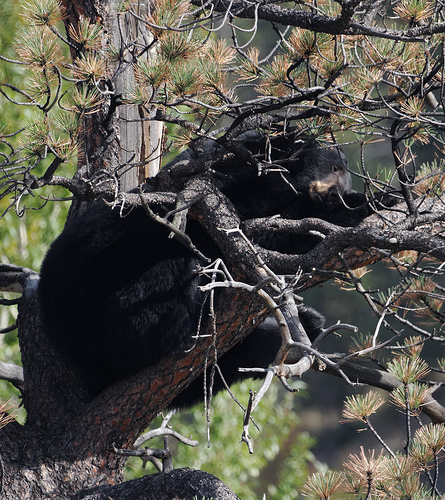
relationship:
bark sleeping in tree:
[0, 441, 124, 500] [0, 1, 443, 498]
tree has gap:
[6, 88, 430, 497] [131, 35, 150, 187]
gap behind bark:
[131, 35, 150, 187] [0, 441, 124, 500]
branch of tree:
[0, 0, 445, 456] [85, 43, 153, 152]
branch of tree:
[0, 0, 445, 456] [5, 60, 403, 496]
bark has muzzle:
[0, 441, 124, 500] [305, 155, 355, 200]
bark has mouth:
[0, 441, 124, 500] [309, 167, 342, 220]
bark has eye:
[0, 441, 124, 500] [332, 161, 343, 174]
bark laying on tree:
[0, 441, 124, 500] [0, 1, 443, 498]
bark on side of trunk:
[14, 439, 115, 479] [6, 395, 177, 492]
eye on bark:
[328, 162, 339, 174] [0, 441, 124, 500]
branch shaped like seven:
[0, 0, 445, 456] [236, 363, 272, 453]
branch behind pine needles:
[38, 22, 443, 330] [64, 18, 105, 51]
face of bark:
[309, 148, 357, 211] [0, 441, 124, 500]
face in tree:
[309, 148, 357, 211] [58, 3, 424, 144]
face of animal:
[309, 154, 350, 206] [27, 129, 380, 379]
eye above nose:
[332, 165, 337, 173] [323, 180, 339, 200]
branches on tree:
[189, 0, 444, 55] [0, 1, 443, 498]